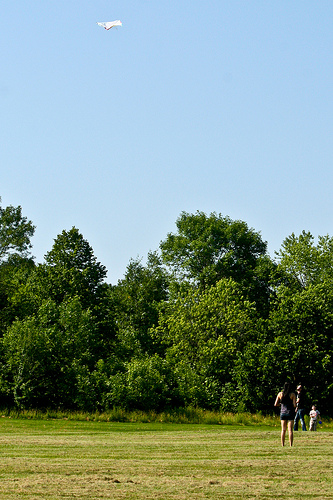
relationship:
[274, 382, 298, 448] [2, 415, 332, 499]
person on grass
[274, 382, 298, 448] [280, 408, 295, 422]
person has on shorts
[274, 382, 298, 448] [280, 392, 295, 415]
person has on a shirt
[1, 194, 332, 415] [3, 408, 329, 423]
tree next to weeds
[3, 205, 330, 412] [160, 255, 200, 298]
leaves are on branches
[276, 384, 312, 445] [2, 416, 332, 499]
people are on a field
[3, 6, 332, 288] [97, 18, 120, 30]
sky has a kite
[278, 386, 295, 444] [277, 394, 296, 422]
person wearing clothes